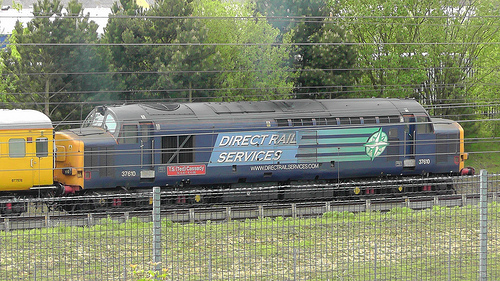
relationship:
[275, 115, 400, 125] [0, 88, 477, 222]
vents on train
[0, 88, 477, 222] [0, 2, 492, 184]
train going through forest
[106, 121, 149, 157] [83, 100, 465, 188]
window on train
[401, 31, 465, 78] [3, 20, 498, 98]
trees in background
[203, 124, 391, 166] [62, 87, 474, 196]
logo on side of engine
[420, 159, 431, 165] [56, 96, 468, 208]
numbers on engine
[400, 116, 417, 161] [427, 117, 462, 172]
door near engine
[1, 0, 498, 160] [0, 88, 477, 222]
trees behind train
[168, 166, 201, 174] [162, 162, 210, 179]
white writing on red sign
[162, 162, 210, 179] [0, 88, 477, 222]
red sign on train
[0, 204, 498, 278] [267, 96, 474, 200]
fence alongside train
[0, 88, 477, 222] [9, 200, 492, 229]
train on track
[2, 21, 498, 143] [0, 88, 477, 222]
trees behind train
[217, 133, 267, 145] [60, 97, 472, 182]
word on train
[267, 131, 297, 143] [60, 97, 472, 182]
word on train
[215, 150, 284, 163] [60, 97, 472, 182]
word on train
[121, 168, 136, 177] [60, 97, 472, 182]
numbers on train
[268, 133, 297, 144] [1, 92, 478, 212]
word on train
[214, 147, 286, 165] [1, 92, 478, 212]
word on train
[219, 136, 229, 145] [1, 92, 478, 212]
letter on train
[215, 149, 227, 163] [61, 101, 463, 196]
letter s on train